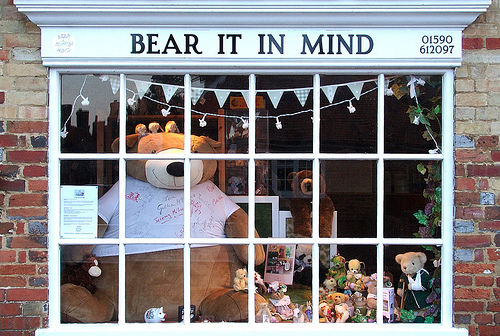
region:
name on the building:
[122, 25, 377, 59]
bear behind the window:
[60, 120, 272, 324]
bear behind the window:
[277, 164, 337, 243]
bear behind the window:
[386, 248, 443, 320]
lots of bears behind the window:
[317, 242, 377, 322]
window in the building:
[55, 70, 445, 323]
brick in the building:
[453, 233, 492, 247]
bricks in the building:
[456, 176, 497, 318]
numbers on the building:
[409, 27, 459, 59]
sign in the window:
[58, 182, 104, 246]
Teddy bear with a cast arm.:
[395, 257, 432, 311]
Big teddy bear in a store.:
[61, 130, 269, 320]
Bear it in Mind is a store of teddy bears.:
[131, 33, 375, 55]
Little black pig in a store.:
[143, 306, 167, 321]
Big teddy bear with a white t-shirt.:
[61, 131, 266, 322]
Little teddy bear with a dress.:
[266, 281, 300, 322]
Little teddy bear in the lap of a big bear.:
[231, 265, 250, 292]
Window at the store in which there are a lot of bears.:
[51, 68, 453, 332]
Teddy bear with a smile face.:
[63, 132, 263, 322]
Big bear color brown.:
[67, 132, 269, 322]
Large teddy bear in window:
[49, 104, 229, 324]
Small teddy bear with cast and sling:
[388, 257, 439, 332]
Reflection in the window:
[127, 244, 172, 291]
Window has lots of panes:
[105, 73, 416, 333]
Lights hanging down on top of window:
[100, 79, 430, 147]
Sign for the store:
[93, 21, 376, 70]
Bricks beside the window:
[2, 151, 37, 311]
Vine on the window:
[408, 79, 460, 269]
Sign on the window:
[57, 183, 104, 240]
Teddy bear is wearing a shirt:
[96, 163, 273, 256]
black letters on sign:
[107, 20, 387, 82]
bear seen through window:
[61, 114, 290, 319]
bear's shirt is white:
[85, 178, 220, 247]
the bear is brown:
[72, 126, 295, 307]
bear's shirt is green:
[385, 251, 438, 306]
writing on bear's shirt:
[93, 179, 239, 236]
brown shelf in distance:
[219, 96, 290, 214]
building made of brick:
[0, 3, 499, 330]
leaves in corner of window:
[395, 91, 450, 330]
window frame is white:
[50, 67, 452, 328]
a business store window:
[12, 14, 499, 310]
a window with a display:
[10, 21, 480, 333]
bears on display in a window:
[14, 33, 484, 335]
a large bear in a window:
[12, 36, 476, 326]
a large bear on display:
[32, 91, 428, 335]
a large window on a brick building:
[14, 32, 499, 319]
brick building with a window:
[0, 14, 495, 319]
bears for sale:
[29, 75, 468, 335]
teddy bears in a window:
[44, 93, 475, 333]